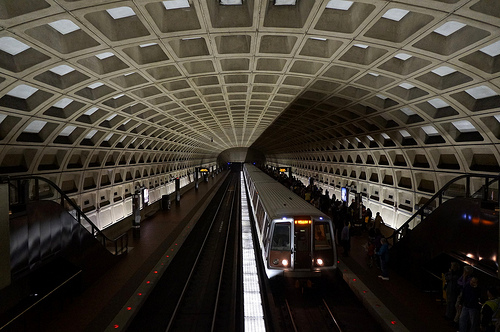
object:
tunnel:
[5, 1, 495, 329]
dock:
[66, 180, 178, 297]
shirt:
[358, 232, 431, 265]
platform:
[280, 161, 479, 326]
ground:
[178, 193, 200, 211]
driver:
[312, 223, 329, 242]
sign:
[292, 215, 312, 225]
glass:
[102, 6, 137, 21]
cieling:
[224, 4, 470, 101]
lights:
[235, 168, 267, 329]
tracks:
[278, 284, 300, 330]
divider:
[237, 166, 262, 330]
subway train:
[250, 197, 382, 302]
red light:
[134, 290, 145, 298]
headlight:
[316, 256, 324, 265]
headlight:
[281, 255, 288, 265]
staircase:
[3, 173, 129, 330]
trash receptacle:
[159, 191, 172, 213]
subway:
[5, 1, 499, 328]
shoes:
[382, 273, 388, 282]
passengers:
[255, 155, 443, 303]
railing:
[421, 172, 480, 203]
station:
[5, 20, 484, 320]